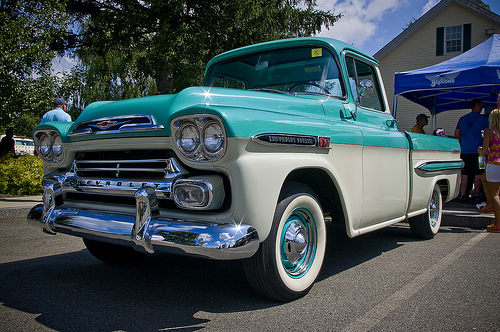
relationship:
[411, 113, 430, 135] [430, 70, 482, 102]
man standing around a tarp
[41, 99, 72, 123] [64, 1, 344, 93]
man standing standing under tree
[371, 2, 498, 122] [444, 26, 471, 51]
building in bathroom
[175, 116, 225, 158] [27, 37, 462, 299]
headlight on car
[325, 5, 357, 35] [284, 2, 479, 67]
cloud in sky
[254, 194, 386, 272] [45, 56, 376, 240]
tire for car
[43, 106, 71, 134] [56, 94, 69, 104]
man wearing cap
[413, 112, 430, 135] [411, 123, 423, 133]
man wearing orange shirt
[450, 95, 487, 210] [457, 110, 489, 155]
man wearing shirt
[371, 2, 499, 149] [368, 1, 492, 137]
building with siding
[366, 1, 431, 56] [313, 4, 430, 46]
sky with clouds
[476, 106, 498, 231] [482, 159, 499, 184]
woman in shorts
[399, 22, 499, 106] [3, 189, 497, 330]
blue canopy in driveway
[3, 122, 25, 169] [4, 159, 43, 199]
person behind a bush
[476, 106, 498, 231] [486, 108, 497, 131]
woman with hair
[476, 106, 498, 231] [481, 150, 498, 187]
woman wearing shorts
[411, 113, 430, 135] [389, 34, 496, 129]
man standing beneath a canopy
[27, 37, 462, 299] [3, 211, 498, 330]
car parked in parking space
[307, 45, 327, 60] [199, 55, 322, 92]
sticker on windsheild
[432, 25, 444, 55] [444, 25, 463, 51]
shutter on window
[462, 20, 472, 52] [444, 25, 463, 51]
shutter on window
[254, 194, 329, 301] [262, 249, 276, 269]
tire has part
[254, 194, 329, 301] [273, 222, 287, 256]
tire has part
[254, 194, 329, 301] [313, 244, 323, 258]
tire has part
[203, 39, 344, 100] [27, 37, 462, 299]
window of a car